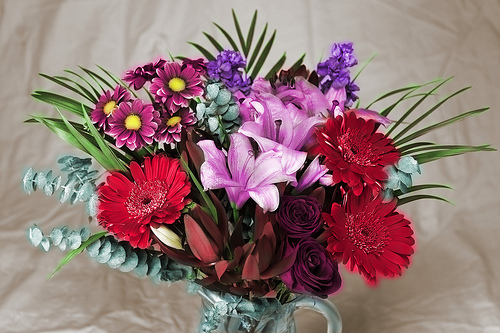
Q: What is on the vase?
A: Flowers.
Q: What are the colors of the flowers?
A: Pink, red, violet.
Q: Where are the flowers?
A: In the vase.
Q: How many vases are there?
A: One.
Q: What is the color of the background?
A: Beige.